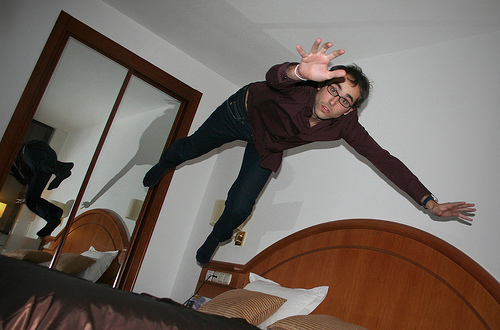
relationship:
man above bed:
[143, 39, 477, 266] [0, 219, 499, 329]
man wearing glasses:
[143, 39, 477, 266] [323, 80, 356, 111]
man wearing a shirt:
[143, 39, 477, 266] [247, 61, 432, 205]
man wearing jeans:
[143, 39, 477, 266] [151, 82, 273, 245]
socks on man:
[143, 161, 219, 266] [143, 39, 477, 266]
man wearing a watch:
[143, 39, 477, 266] [422, 193, 437, 210]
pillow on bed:
[198, 289, 288, 326] [0, 219, 499, 329]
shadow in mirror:
[80, 94, 182, 209] [0, 9, 203, 291]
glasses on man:
[323, 80, 356, 111] [143, 39, 477, 266]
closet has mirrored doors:
[1, 8, 204, 293] [4, 37, 181, 287]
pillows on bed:
[198, 272, 369, 330] [0, 219, 499, 329]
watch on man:
[422, 193, 437, 210] [143, 39, 477, 266]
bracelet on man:
[294, 63, 308, 83] [143, 39, 477, 266]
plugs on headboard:
[205, 269, 233, 285] [195, 218, 499, 329]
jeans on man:
[151, 82, 273, 245] [143, 39, 477, 266]